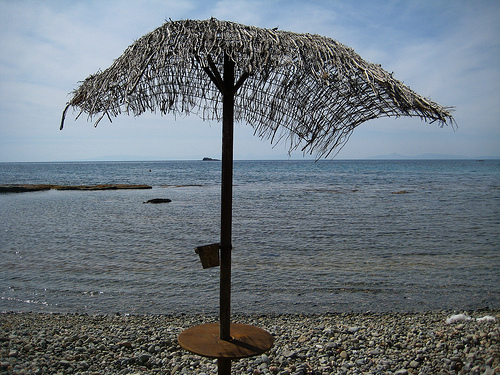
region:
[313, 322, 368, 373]
part of a groubnd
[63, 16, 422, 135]
grey umbrella on rocks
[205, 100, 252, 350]
black post of umbrella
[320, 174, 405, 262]
few ripples on water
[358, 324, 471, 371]
grey rocks on beach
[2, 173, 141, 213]
brown rocks in water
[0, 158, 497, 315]
the body of water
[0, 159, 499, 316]
the calm water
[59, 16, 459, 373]
the old straw umbrella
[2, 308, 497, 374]
the rocks on the ground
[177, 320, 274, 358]
the small round table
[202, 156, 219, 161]
the small island in the distance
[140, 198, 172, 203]
the large rock in the water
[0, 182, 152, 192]
the long flat rocks in the water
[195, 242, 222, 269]
the small bucket on the pole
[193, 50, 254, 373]
the pole for the straw umbrella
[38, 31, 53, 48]
this is the sky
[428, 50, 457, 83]
the sky has clouds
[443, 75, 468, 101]
the clouds are white in color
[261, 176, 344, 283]
this is the water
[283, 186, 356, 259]
the water has ripples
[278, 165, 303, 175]
the water is blue in color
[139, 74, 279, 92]
this is an umbrella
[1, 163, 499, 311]
light blue body of water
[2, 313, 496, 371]
rocks along the shore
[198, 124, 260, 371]
umbrella rod sticking in the ground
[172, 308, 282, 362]
round piece of wood attached to the rod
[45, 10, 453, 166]
top of the umbrella is straw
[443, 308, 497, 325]
white object laying on the shore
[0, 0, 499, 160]
thin white clouds in the sky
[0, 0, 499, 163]
blue and white sky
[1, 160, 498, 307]
large body of water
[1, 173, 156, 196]
rocks sticking out of the water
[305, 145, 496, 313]
a body of water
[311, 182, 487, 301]
a body of calm water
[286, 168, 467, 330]
a body of water is calm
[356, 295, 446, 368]
a beach covered in rocks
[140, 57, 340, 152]
a net above the table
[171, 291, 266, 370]
a circle table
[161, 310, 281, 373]
a wood circle table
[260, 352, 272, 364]
Small rock next to a rock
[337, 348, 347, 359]
Small rock next to a rock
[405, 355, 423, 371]
Small rock next to a rock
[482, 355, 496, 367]
Small rock next to a rock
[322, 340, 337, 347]
Small rock next to a rock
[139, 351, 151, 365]
Small rock next to a rock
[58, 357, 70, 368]
Small rock next to a rock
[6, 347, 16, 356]
Small rock next to a rock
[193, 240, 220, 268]
Small bucket hanging from the pole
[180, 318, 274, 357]
Small round brown table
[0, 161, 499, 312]
a large body of water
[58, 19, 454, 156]
a worn patio umbrella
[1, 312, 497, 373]
a rocky beach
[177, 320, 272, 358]
a small brown patio table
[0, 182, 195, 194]
a small land protrusion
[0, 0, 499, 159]
a cloudy blue sky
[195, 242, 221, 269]
a black cup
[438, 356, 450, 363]
a large grey rock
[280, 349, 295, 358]
a large grey rock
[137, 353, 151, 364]
a large grey rock